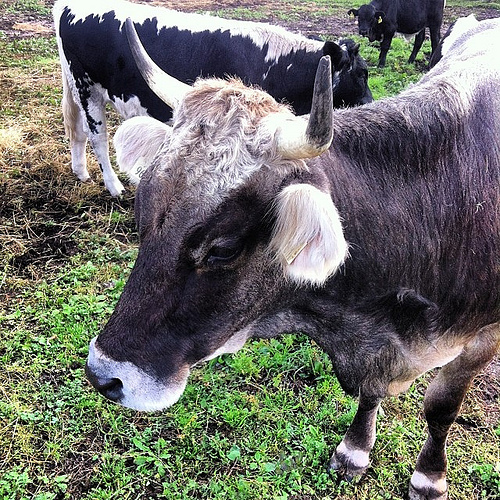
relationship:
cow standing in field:
[353, 0, 445, 62] [0, 3, 499, 495]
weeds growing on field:
[2, 250, 498, 497] [4, 1, 499, 496]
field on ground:
[0, 3, 499, 495] [3, 0, 489, 495]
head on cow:
[27, 66, 334, 444] [87, 17, 497, 494]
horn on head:
[125, 11, 195, 110] [27, 66, 334, 444]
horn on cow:
[125, 11, 195, 110] [87, 17, 497, 494]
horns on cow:
[106, 17, 359, 167] [45, 55, 498, 417]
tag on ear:
[267, 220, 312, 263] [271, 163, 346, 285]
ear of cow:
[271, 163, 346, 285] [87, 17, 497, 494]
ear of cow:
[113, 116, 169, 186] [87, 17, 497, 494]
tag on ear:
[128, 158, 145, 182] [113, 116, 169, 186]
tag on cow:
[128, 158, 145, 182] [87, 17, 497, 494]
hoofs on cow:
[331, 418, 429, 498] [87, 17, 497, 494]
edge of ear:
[319, 194, 347, 286] [274, 171, 349, 288]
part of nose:
[101, 370, 140, 404] [83, 335, 192, 413]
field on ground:
[0, 3, 499, 495] [450, 146, 465, 159]